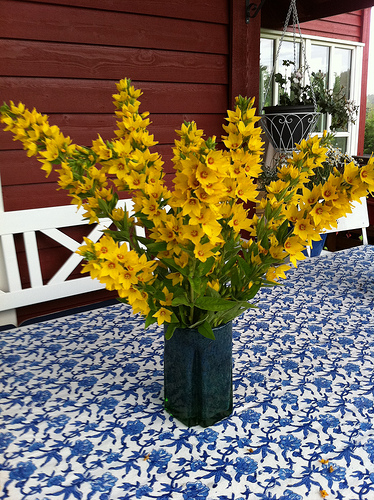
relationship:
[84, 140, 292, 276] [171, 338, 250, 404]
flower in vase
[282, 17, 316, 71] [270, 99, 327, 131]
chain on basket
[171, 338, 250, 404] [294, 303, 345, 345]
vase on table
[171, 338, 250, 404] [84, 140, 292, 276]
vase has flower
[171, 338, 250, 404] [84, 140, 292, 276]
vase holding flower